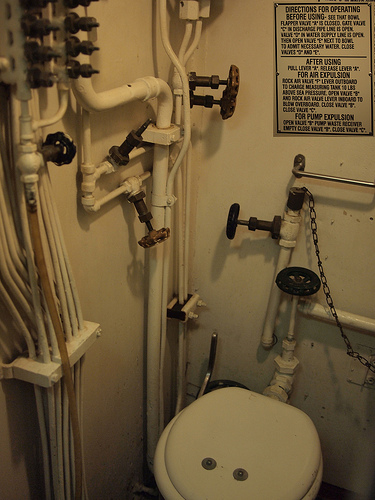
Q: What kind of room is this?
A: It is a bathroom.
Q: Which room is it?
A: It is a bathroom.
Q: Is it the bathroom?
A: Yes, it is the bathroom.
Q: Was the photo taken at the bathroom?
A: Yes, it was taken in the bathroom.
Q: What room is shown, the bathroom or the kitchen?
A: It is the bathroom.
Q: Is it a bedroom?
A: No, it is a bathroom.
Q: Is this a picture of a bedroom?
A: No, the picture is showing a bathroom.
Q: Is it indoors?
A: Yes, it is indoors.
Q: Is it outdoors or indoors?
A: It is indoors.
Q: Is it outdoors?
A: No, it is indoors.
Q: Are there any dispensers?
A: No, there are no dispensers.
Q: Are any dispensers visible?
A: No, there are no dispensers.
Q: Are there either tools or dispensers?
A: No, there are no dispensers or tools.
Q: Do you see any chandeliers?
A: No, there are no chandeliers.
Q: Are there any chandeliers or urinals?
A: No, there are no chandeliers or urinals.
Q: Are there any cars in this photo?
A: No, there are no cars.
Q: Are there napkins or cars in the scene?
A: No, there are no cars or napkins.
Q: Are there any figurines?
A: No, there are no figurines.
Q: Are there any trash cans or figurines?
A: No, there are no figurines or trash cans.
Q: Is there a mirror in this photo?
A: No, there are no mirrors.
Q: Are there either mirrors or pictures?
A: No, there are no mirrors or pictures.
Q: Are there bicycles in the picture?
A: No, there are no bicycles.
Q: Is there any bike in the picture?
A: No, there are no bikes.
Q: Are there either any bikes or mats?
A: No, there are no bikes or mats.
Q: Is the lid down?
A: Yes, the lid is down.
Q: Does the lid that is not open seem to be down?
A: Yes, the lid is down.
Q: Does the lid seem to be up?
A: No, the lid is down.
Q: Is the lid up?
A: No, the lid is down.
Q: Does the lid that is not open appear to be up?
A: No, the lid is down.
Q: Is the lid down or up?
A: The lid is down.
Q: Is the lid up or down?
A: The lid is down.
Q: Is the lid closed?
A: Yes, the lid is closed.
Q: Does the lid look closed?
A: Yes, the lid is closed.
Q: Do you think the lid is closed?
A: Yes, the lid is closed.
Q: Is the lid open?
A: No, the lid is closed.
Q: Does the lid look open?
A: No, the lid is closed.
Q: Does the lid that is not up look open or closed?
A: The lid is closed.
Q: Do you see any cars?
A: No, there are no cars.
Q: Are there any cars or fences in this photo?
A: No, there are no cars or fences.